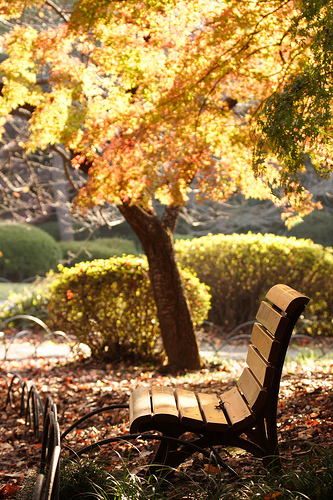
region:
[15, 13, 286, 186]
fall leaves on tree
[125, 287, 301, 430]
a small park bench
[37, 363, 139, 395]
fall leaves on ground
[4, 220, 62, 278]
a round green shrub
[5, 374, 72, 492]
rounded black garden gate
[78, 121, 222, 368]
brown tree with colored leaves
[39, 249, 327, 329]
a tall tree and two shrubs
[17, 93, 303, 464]
a tree and a bench in a park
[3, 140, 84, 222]
a tree with no leaves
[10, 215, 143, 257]
tree rounded bushes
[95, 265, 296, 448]
an empty wooden bench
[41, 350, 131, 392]
dry leaves on the ground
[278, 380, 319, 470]
dry leaves on the ground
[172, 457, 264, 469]
dry leaves on the ground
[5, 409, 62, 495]
dry leaves on the ground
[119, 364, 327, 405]
dry leaves on the ground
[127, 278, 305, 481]
a wooden park bench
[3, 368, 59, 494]
a small black wire fence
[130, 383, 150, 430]
a brown wood slat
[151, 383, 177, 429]
a brown wood slat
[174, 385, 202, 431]
a brown wood slat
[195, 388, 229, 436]
a brown wood slat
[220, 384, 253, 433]
a brown wood slat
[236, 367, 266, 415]
a brown wood slat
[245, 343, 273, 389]
a brown wood slat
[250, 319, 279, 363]
a brown wood slat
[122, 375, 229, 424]
surface of brown bench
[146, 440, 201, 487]
base of brown bench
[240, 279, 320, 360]
top of brown bench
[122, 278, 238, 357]
tree by the bench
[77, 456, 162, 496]
grass by the bench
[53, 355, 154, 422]
bundles of leaves on ground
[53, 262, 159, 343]
green bush by tree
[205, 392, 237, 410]
small object on bench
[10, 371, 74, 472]
rail by the bench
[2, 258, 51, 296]
trees in the corner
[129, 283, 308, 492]
a bench is in a park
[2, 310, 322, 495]
a loop wire fence is around the bench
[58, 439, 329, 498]
green plant leaves are next to the bench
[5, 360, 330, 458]
brown and orange leaves are on the ground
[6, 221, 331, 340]
bushes are growing in the park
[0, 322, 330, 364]
a walkway is near the bench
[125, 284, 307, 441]
the bench has wooden slats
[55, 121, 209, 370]
a tree trunk is next to the pathway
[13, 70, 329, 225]
the leaves of the tree are yellow and orange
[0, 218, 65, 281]
the bush has been trimmed to be round